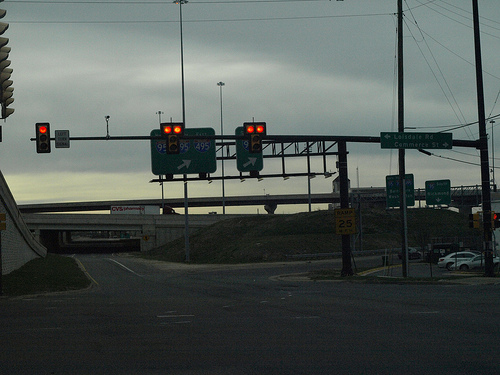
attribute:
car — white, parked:
[439, 249, 485, 272]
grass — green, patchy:
[0, 252, 92, 296]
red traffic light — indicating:
[244, 121, 269, 155]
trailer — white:
[110, 202, 161, 216]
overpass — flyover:
[20, 188, 338, 233]